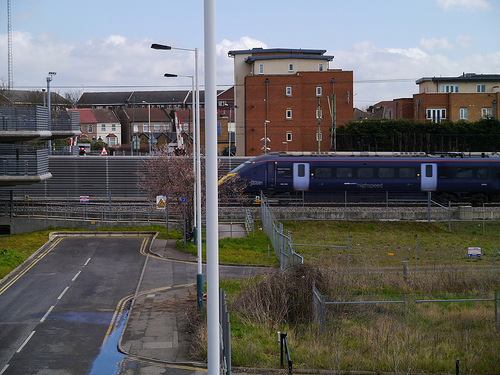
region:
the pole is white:
[189, 22, 240, 350]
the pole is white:
[178, 48, 216, 259]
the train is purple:
[219, 130, 496, 222]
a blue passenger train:
[218, 155, 495, 200]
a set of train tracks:
[3, 198, 498, 208]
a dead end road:
[0, 232, 154, 373]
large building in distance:
[78, 89, 188, 108]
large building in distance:
[225, 45, 355, 154]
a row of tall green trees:
[337, 119, 497, 154]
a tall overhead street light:
[147, 41, 205, 309]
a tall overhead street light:
[162, 72, 197, 247]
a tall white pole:
[202, 0, 217, 374]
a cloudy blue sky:
[0, 0, 498, 112]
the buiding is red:
[248, 70, 295, 159]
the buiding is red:
[285, 85, 342, 148]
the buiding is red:
[255, 80, 357, 167]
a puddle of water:
[85, 309, 151, 374]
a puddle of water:
[78, 320, 131, 370]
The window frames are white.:
[281, 86, 297, 144]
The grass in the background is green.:
[338, 231, 384, 248]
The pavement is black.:
[75, 289, 92, 339]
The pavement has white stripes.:
[38, 276, 70, 337]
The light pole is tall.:
[206, 5, 223, 372]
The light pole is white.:
[208, 1, 218, 372]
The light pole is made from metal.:
[204, 0, 223, 371]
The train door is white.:
[292, 161, 309, 193]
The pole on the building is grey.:
[263, 74, 269, 121]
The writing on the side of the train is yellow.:
[356, 180, 386, 188]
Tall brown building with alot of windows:
[239, 58, 362, 156]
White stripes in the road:
[2, 239, 112, 374]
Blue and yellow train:
[222, 151, 497, 208]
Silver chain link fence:
[250, 195, 499, 341]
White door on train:
[291, 158, 318, 193]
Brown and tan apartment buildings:
[366, 60, 499, 131]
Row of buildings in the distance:
[51, 96, 240, 161]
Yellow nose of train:
[212, 164, 249, 202]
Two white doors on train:
[289, 161, 440, 200]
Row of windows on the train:
[267, 161, 499, 186]